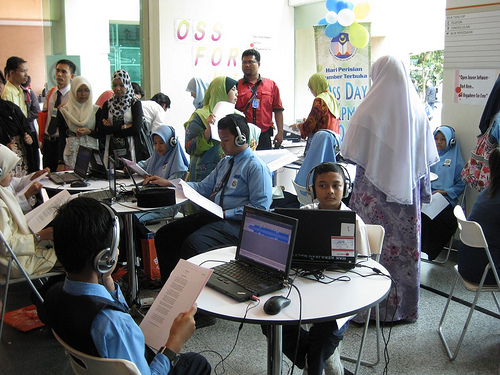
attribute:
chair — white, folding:
[351, 227, 390, 260]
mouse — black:
[245, 287, 294, 309]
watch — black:
[161, 346, 182, 357]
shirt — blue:
[74, 249, 168, 370]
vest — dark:
[22, 286, 122, 346]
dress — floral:
[360, 172, 422, 325]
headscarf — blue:
[145, 120, 186, 171]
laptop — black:
[215, 212, 307, 315]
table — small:
[197, 226, 397, 328]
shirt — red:
[229, 83, 283, 138]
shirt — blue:
[191, 143, 279, 209]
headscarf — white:
[347, 55, 436, 206]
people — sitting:
[4, 32, 497, 356]